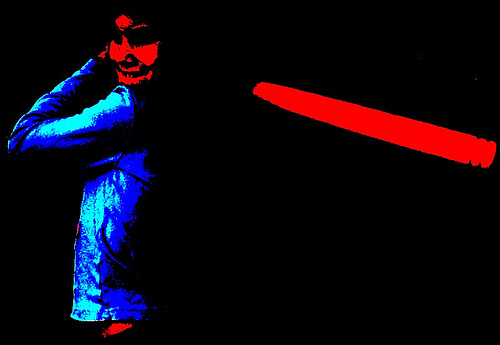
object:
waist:
[80, 307, 160, 340]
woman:
[2, 13, 179, 337]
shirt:
[6, 56, 165, 324]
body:
[7, 11, 174, 336]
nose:
[124, 53, 137, 65]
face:
[99, 8, 172, 84]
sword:
[252, 81, 496, 168]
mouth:
[117, 64, 147, 77]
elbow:
[56, 116, 88, 140]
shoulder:
[113, 82, 153, 110]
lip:
[116, 66, 147, 76]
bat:
[251, 82, 496, 170]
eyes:
[106, 27, 161, 46]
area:
[0, 0, 497, 345]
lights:
[80, 190, 104, 320]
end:
[468, 135, 497, 168]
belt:
[67, 303, 153, 324]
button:
[76, 223, 81, 237]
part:
[102, 322, 134, 338]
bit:
[75, 223, 80, 236]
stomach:
[85, 287, 149, 317]